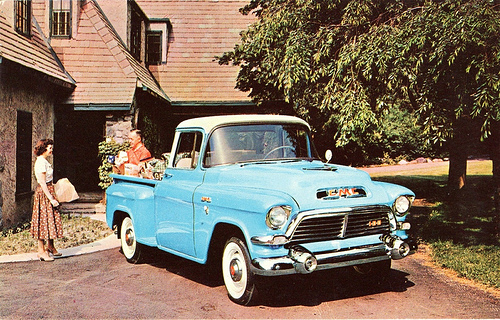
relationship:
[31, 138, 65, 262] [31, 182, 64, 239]
woman wearing skirt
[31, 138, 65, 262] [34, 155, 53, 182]
woman wearing blouse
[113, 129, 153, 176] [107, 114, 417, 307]
man standing by truck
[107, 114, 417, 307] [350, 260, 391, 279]
truck has wheel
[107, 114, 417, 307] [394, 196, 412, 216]
truck has headlight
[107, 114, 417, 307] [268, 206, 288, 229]
truck has headlight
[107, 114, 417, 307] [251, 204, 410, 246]
truck has grill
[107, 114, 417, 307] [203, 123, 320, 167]
truck has windshield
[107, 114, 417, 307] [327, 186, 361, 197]
truck has logo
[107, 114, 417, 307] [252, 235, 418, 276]
truck has bumper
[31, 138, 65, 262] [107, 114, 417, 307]
woman by truck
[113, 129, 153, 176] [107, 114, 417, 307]
man by truck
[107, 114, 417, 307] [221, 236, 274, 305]
truck has wheel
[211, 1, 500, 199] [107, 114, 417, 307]
tree beside truck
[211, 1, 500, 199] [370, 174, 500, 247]
tree has shadow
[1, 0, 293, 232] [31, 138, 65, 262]
house beside woman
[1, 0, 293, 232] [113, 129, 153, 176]
house beside man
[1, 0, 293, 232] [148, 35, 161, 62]
house has window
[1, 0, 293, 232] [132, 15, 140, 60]
house has window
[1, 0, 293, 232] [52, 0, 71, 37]
house has window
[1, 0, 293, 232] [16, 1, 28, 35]
house has window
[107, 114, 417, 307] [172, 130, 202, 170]
truck has window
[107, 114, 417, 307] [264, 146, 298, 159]
truck has steering wheel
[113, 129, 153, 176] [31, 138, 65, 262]
man next to woman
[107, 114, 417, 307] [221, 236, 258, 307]
truck has wheel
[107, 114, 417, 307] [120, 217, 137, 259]
truck has white wall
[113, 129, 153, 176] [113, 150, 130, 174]
man holding groceries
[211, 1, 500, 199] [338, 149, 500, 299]
tree in yard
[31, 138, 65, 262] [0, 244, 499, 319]
woman standing in driveway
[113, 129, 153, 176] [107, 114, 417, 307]
man behind truck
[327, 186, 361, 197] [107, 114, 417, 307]
logo on truck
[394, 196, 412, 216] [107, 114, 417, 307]
headlight on truck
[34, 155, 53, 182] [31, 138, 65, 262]
blouse on woman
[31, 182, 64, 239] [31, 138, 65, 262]
skirt on woman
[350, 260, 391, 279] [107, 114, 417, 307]
wheel on truck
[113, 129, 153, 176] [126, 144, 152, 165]
man wearing shirt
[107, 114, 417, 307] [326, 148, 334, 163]
truck has rear view mirror